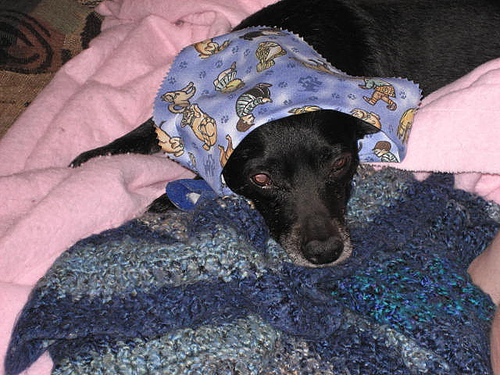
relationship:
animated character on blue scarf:
[233, 81, 275, 134] [0, 160, 500, 374]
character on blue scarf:
[257, 38, 285, 73] [0, 160, 500, 374]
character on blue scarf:
[359, 79, 396, 111] [0, 160, 500, 374]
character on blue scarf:
[181, 103, 216, 148] [0, 160, 500, 374]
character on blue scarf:
[372, 140, 399, 162] [0, 160, 500, 374]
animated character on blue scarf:
[233, 80, 275, 135] [161, 23, 416, 191]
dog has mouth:
[78, 17, 493, 267] [274, 219, 353, 269]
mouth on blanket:
[274, 219, 353, 269] [2, 166, 499, 373]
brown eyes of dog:
[244, 151, 349, 189] [78, 17, 493, 267]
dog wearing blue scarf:
[66, 0, 500, 267] [0, 160, 500, 374]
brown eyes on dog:
[249, 170, 279, 191] [78, 17, 493, 267]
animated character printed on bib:
[233, 81, 275, 134] [158, 43, 429, 174]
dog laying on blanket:
[78, 17, 493, 267] [4, 4, 461, 356]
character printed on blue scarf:
[357, 76, 396, 111] [0, 160, 500, 374]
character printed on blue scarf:
[349, 107, 384, 131] [0, 160, 500, 374]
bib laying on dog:
[147, 25, 428, 203] [63, 3, 498, 278]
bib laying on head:
[147, 25, 428, 203] [206, 93, 394, 275]